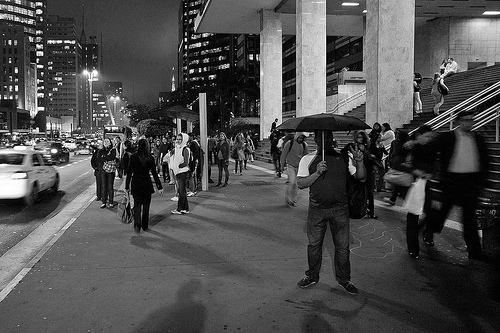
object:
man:
[423, 112, 493, 263]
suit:
[440, 130, 491, 194]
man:
[410, 72, 421, 115]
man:
[185, 133, 205, 197]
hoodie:
[162, 133, 190, 176]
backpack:
[289, 140, 306, 153]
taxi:
[2, 141, 62, 211]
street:
[2, 138, 499, 333]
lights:
[0, 17, 132, 138]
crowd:
[90, 129, 256, 235]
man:
[279, 132, 310, 207]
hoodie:
[280, 132, 310, 168]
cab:
[4, 146, 61, 207]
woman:
[431, 72, 451, 115]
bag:
[438, 83, 452, 95]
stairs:
[241, 64, 500, 239]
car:
[0, 146, 61, 205]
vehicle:
[34, 141, 69, 165]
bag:
[103, 160, 118, 173]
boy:
[169, 131, 198, 214]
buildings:
[172, 1, 259, 133]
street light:
[82, 69, 98, 81]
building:
[45, 20, 85, 135]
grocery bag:
[401, 176, 429, 223]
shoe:
[337, 279, 359, 295]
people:
[124, 138, 165, 232]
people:
[213, 131, 231, 187]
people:
[97, 138, 116, 209]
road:
[0, 144, 99, 306]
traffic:
[1, 128, 101, 207]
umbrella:
[276, 113, 374, 172]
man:
[296, 129, 364, 296]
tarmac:
[0, 159, 499, 333]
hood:
[175, 132, 190, 147]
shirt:
[296, 149, 358, 208]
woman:
[382, 125, 440, 259]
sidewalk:
[0, 160, 499, 332]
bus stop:
[90, 109, 209, 231]